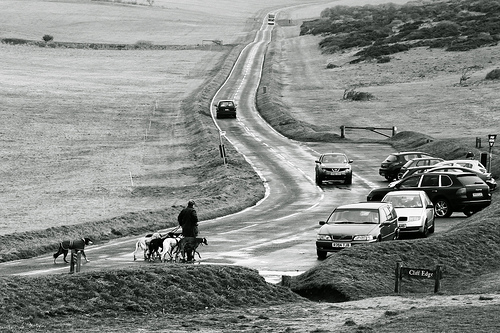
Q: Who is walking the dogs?
A: The man.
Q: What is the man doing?
A: Walking dogs.